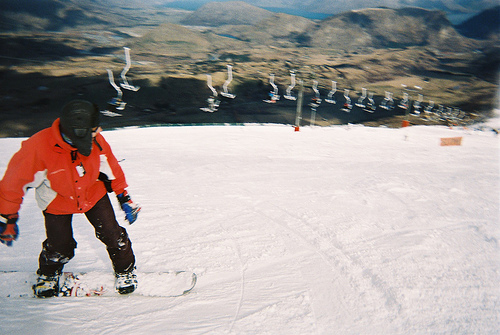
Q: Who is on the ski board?
A: The man.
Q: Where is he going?
A: Skiing.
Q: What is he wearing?
A: Orange jacket.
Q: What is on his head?
A: A helmet.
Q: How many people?
A: One.